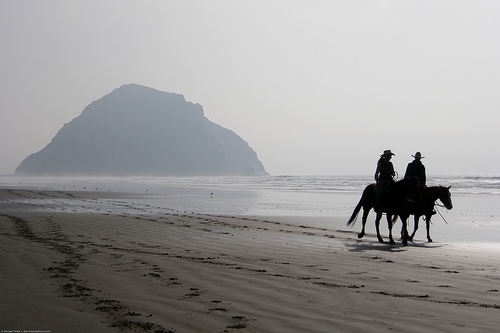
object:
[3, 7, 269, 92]
sky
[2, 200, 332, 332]
beach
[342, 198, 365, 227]
tail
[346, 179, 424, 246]
horse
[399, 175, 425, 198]
head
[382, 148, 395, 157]
hat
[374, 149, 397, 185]
lady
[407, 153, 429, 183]
man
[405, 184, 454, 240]
horse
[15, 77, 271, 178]
hill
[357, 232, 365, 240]
hoof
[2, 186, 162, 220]
sand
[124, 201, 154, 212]
footprints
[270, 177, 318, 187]
water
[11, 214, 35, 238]
tracks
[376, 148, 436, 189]
couple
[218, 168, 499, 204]
sea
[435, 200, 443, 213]
reins